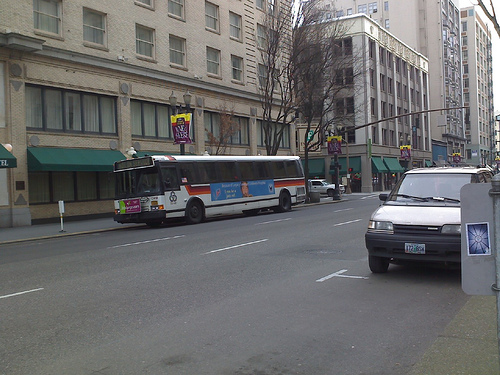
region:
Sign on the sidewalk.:
[52, 195, 70, 234]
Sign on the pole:
[163, 110, 195, 145]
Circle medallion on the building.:
[117, 76, 132, 96]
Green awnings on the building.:
[369, 149, 406, 178]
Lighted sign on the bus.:
[110, 155, 157, 175]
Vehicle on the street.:
[308, 170, 348, 197]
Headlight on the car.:
[363, 216, 395, 236]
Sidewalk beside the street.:
[407, 265, 497, 372]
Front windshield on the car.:
[387, 168, 474, 209]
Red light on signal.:
[345, 163, 357, 174]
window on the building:
[200, 49, 226, 74]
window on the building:
[97, 98, 112, 130]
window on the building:
[77, 95, 102, 130]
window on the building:
[62, 91, 82, 128]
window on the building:
[129, 28, 158, 59]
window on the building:
[228, 56, 249, 82]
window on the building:
[168, 37, 185, 59]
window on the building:
[170, 40, 187, 63]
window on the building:
[231, 58, 243, 75]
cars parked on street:
[89, 139, 458, 282]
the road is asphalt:
[84, 295, 189, 347]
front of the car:
[355, 205, 457, 264]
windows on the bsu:
[168, 162, 301, 180]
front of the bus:
[102, 164, 160, 194]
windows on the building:
[347, 33, 429, 145]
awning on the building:
[41, 143, 116, 169]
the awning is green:
[65, 148, 97, 160]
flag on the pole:
[170, 112, 195, 142]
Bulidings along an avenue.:
[3, 1, 496, 203]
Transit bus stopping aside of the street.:
[105, 150, 310, 230]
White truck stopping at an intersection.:
[306, 172, 341, 207]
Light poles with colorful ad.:
[157, 101, 472, 166]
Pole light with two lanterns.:
[160, 86, 198, 113]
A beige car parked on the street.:
[362, 162, 488, 294]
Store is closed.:
[25, 143, 115, 214]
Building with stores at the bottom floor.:
[305, 16, 431, 196]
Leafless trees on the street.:
[258, 20, 369, 147]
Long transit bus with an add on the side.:
[114, 152, 318, 226]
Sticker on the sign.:
[462, 218, 492, 261]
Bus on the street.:
[110, 148, 311, 230]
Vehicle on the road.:
[361, 155, 493, 290]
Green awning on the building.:
[22, 140, 130, 173]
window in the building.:
[202, 43, 225, 80]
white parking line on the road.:
[310, 262, 368, 289]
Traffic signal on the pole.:
[459, 102, 474, 127]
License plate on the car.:
[397, 238, 428, 254]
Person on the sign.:
[236, 178, 256, 199]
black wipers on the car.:
[388, 190, 462, 206]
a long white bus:
[102, 139, 309, 230]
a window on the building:
[40, 1, 57, 40]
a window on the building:
[75, 9, 98, 29]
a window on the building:
[122, 26, 154, 68]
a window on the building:
[163, 31, 188, 56]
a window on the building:
[195, 46, 216, 63]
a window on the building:
[22, 85, 32, 110]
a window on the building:
[42, 85, 65, 122]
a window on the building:
[76, 89, 93, 130]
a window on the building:
[104, 98, 120, 121]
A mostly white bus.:
[112, 154, 308, 228]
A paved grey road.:
[1, 191, 465, 373]